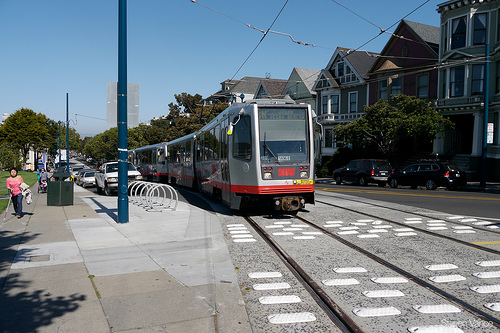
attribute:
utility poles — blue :
[47, 5, 138, 229]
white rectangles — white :
[228, 202, 466, 327]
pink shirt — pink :
[1, 174, 35, 202]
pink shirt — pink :
[6, 175, 25, 194]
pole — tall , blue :
[116, 0, 127, 220]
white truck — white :
[93, 156, 143, 191]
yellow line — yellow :
[310, 182, 498, 207]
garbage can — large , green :
[42, 167, 76, 207]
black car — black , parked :
[384, 158, 468, 191]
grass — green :
[0, 171, 40, 212]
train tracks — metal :
[228, 180, 498, 330]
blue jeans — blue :
[10, 191, 26, 213]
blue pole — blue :
[109, 3, 134, 223]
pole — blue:
[469, 112, 493, 149]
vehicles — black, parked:
[341, 153, 474, 203]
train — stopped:
[119, 92, 303, 215]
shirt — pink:
[10, 178, 40, 202]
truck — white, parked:
[99, 158, 172, 199]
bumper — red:
[232, 171, 319, 211]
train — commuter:
[144, 103, 344, 203]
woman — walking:
[1, 174, 61, 231]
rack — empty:
[126, 171, 199, 215]